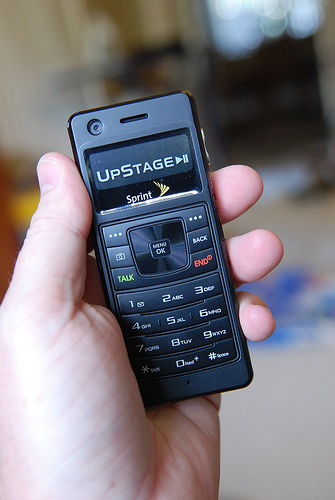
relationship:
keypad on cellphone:
[116, 272, 238, 383] [61, 83, 258, 411]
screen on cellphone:
[82, 125, 204, 214] [61, 83, 258, 411]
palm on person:
[0, 294, 227, 497] [0, 147, 286, 498]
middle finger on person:
[207, 164, 264, 224] [0, 147, 286, 498]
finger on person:
[225, 227, 285, 285] [0, 147, 286, 498]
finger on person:
[236, 286, 275, 343] [0, 147, 286, 498]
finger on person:
[4, 149, 94, 303] [0, 147, 286, 498]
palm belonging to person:
[0, 294, 227, 497] [0, 147, 286, 498]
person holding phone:
[0, 147, 286, 498] [65, 89, 255, 411]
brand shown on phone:
[120, 180, 172, 207] [65, 89, 255, 411]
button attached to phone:
[188, 246, 219, 276] [73, 67, 297, 393]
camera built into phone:
[86, 118, 104, 134] [62, 88, 258, 412]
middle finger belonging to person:
[210, 164, 262, 224] [0, 147, 286, 498]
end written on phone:
[193, 255, 210, 270] [82, 78, 234, 401]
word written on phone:
[192, 233, 207, 245] [71, 89, 254, 393]